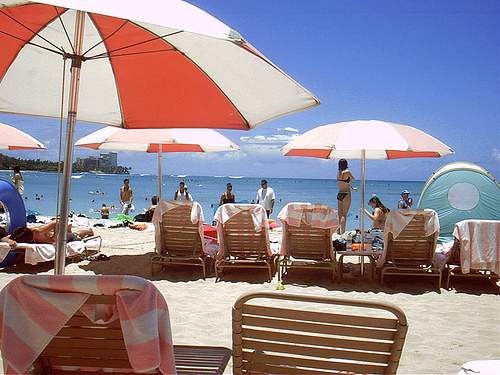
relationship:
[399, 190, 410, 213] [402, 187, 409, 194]
man wears baseball cap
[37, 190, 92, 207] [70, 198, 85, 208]
people in water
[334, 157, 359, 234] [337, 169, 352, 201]
woman wears bikini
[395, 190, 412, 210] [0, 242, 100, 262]
man on chair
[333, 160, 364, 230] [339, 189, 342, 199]
woman wearing bikini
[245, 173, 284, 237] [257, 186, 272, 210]
man wearing shirt